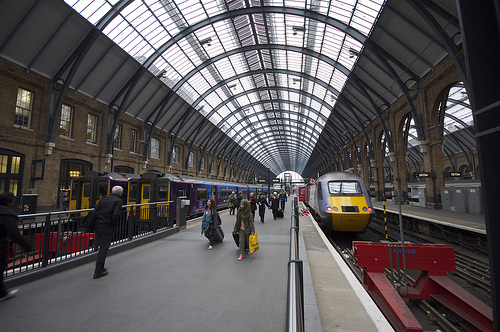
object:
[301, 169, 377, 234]
train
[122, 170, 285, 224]
train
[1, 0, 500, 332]
station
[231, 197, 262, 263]
woman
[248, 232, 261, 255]
bag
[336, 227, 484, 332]
tracks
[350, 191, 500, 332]
barrier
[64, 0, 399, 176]
ceiling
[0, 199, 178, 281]
fence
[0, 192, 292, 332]
platform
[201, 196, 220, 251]
woman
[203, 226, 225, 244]
suitcase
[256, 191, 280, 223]
couple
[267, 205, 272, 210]
hands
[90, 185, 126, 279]
man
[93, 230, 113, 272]
trousers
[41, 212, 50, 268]
post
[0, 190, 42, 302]
man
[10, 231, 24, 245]
elbow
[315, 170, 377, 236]
front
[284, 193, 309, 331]
railing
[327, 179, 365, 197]
window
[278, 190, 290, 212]
person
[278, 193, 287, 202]
jacket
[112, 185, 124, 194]
hair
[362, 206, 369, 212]
headlight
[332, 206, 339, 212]
headlight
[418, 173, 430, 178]
sign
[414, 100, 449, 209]
pillar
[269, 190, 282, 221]
man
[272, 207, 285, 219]
bag